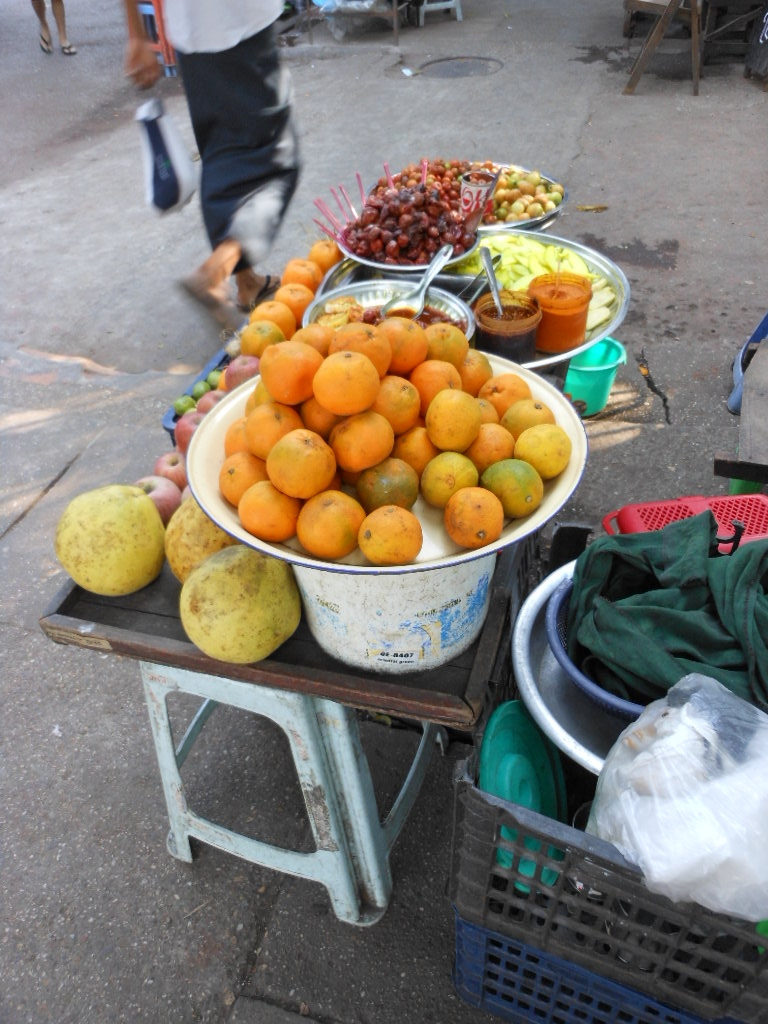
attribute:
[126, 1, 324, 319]
person — walking down the street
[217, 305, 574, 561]
orange fruit — in a white and blue bowl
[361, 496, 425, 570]
orange — small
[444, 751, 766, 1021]
basket — black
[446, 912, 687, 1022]
basket — blue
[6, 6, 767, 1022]
sidewalk — dark gray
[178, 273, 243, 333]
sandal — black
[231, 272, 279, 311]
sandal — black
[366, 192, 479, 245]
cherries — red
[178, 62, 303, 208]
skirt — blue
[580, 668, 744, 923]
bag — white, plastic